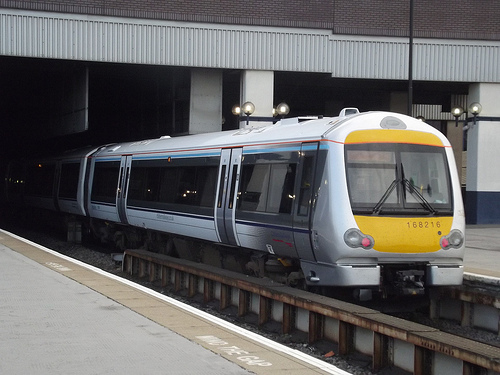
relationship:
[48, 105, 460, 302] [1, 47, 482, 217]
train exiting tunnel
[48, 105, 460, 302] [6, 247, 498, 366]
train on track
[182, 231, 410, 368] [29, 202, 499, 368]
barrier beside track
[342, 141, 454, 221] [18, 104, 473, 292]
windshield of train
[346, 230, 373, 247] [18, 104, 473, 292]
headlight of train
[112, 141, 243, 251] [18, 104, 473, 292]
doors on train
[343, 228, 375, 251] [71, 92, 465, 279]
headlight on front of train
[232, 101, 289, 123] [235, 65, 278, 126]
lights on front of column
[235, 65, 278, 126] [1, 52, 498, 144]
column on tunnel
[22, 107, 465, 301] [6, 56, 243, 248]
train emerging from tunnel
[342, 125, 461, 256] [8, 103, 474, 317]
front of train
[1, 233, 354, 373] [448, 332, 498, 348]
platform next to tracks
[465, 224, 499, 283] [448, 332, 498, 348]
platform next to tracks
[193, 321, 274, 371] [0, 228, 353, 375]
writing on platform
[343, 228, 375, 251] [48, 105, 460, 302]
headlight on train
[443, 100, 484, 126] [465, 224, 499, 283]
lighting for platform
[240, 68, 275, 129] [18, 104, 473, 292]
column behind train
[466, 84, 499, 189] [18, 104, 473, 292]
pillar behind train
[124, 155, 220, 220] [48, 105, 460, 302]
window on train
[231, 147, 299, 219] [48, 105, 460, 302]
window on train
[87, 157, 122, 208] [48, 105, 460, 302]
window on train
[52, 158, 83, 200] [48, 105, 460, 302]
window on train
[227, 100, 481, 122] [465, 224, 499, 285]
lights over platform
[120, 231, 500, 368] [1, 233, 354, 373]
barrier of platform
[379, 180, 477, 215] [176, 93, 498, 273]
wiper on train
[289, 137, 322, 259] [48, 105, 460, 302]
door on train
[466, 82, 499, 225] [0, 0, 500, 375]
pillar at station